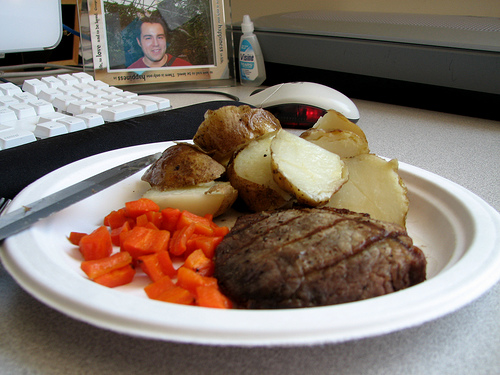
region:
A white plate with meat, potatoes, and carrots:
[10, 102, 498, 349]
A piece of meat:
[207, 197, 432, 314]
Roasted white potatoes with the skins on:
[135, 98, 430, 225]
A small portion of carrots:
[70, 193, 235, 305]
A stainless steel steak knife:
[0, 150, 162, 240]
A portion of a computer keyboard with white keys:
[0, 69, 169, 149]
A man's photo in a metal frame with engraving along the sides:
[84, 0, 233, 83]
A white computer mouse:
[235, 79, 364, 131]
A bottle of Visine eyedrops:
[235, 11, 270, 88]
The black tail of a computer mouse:
[136, 87, 245, 103]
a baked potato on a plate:
[120, 118, 385, 210]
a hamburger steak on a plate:
[211, 225, 426, 320]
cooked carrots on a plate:
[47, 197, 212, 316]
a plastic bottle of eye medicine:
[235, 9, 263, 96]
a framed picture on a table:
[59, 11, 240, 88]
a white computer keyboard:
[0, 73, 144, 139]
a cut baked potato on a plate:
[107, 128, 377, 198]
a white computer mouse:
[220, 68, 355, 131]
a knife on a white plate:
[0, 148, 159, 245]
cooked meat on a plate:
[293, 206, 433, 325]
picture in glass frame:
[77, 0, 237, 92]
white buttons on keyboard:
[0, 71, 167, 145]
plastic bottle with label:
[237, 14, 267, 84]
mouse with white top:
[246, 78, 362, 125]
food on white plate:
[2, 102, 497, 347]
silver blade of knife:
[0, 153, 161, 240]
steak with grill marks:
[218, 209, 420, 299]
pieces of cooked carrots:
[78, 198, 229, 308]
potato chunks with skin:
[153, 103, 408, 223]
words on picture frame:
[109, 68, 217, 85]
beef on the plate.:
[214, 199, 430, 306]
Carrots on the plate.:
[62, 190, 227, 312]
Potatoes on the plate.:
[144, 104, 420, 235]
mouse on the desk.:
[238, 70, 360, 131]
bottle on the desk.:
[234, 16, 270, 90]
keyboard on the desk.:
[0, 67, 174, 156]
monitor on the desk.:
[0, 3, 80, 70]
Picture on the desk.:
[85, 0, 232, 87]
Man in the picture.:
[125, 10, 193, 66]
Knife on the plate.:
[4, 135, 162, 253]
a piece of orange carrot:
[144, 277, 191, 310]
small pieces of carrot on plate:
[79, 199, 234, 310]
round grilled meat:
[212, 207, 424, 308]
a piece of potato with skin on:
[269, 120, 351, 206]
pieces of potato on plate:
[142, 102, 413, 228]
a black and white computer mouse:
[239, 74, 360, 129]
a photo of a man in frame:
[81, 0, 237, 92]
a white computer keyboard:
[0, 65, 173, 150]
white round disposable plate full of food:
[6, 127, 498, 349]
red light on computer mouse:
[299, 103, 324, 124]